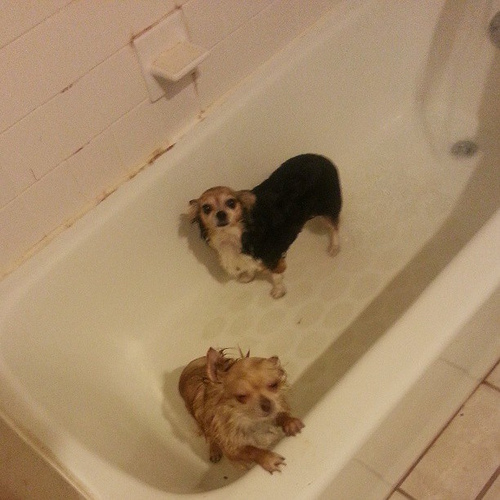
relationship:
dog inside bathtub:
[187, 153, 344, 300] [35, 84, 465, 412]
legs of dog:
[234, 224, 356, 299] [187, 153, 344, 300]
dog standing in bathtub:
[187, 153, 344, 300] [5, 5, 499, 494]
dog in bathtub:
[187, 153, 344, 300] [100, 65, 467, 347]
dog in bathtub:
[187, 153, 344, 300] [5, 5, 499, 494]